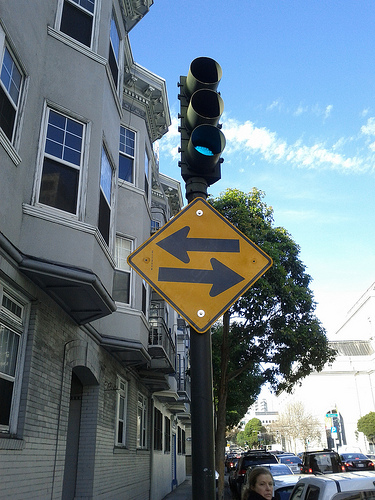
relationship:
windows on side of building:
[110, 372, 174, 457] [0, 0, 191, 498]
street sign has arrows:
[126, 196, 272, 335] [156, 224, 245, 298]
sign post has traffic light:
[177, 55, 224, 499] [176, 55, 225, 183]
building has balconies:
[0, 0, 191, 498] [144, 304, 195, 412]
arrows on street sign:
[156, 224, 245, 298] [126, 196, 272, 335]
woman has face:
[237, 466, 275, 500] [255, 472, 274, 499]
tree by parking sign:
[355, 410, 374, 446] [330, 426, 338, 430]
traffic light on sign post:
[176, 55, 225, 183] [177, 55, 224, 499]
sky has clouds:
[132, 0, 370, 337] [153, 98, 374, 169]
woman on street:
[237, 466, 275, 500] [226, 456, 373, 499]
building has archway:
[0, 0, 191, 498] [52, 341, 103, 499]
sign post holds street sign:
[177, 55, 224, 499] [126, 196, 272, 335]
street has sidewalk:
[226, 456, 373, 499] [158, 471, 229, 499]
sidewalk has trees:
[158, 471, 229, 499] [189, 186, 333, 499]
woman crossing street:
[237, 466, 275, 500] [226, 456, 373, 499]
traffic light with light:
[176, 55, 225, 183] [186, 125, 226, 170]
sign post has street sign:
[177, 55, 224, 499] [126, 196, 272, 335]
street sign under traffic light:
[126, 196, 272, 335] [176, 55, 225, 183]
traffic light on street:
[176, 55, 225, 183] [226, 456, 373, 499]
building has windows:
[0, 0, 191, 498] [0, 0, 187, 457]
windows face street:
[0, 0, 187, 457] [226, 456, 373, 499]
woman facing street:
[237, 466, 275, 500] [226, 456, 373, 499]